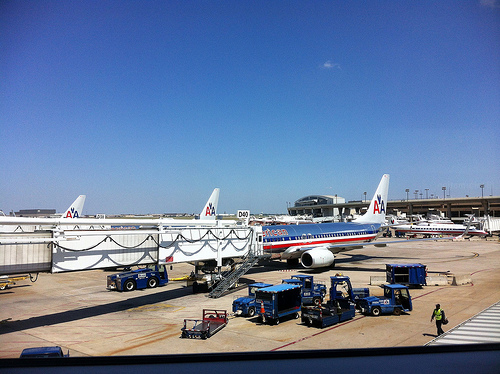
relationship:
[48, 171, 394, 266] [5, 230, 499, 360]
airplanes on runway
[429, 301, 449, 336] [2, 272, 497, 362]
man walking on runway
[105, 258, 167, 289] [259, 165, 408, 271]
machine parked near airplane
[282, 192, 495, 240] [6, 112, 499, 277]
building in background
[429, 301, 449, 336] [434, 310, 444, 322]
man wearing vest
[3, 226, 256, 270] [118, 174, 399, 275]
an extension between planes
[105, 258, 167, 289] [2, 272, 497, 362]
machine on runway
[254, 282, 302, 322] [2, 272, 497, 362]
blue machine on runway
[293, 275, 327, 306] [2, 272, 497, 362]
machine on runway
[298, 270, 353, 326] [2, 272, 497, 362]
blue vehicle on runway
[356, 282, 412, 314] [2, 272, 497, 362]
machine on runway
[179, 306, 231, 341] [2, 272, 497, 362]
machine on runway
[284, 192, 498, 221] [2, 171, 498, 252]
terminal in background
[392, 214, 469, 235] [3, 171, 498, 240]
airplane in background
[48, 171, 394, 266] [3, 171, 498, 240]
airplanes in background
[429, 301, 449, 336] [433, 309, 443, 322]
man wearing a green vest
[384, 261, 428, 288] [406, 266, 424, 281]
luggage cart has a curtain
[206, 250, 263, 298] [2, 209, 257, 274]
ladder leading to gate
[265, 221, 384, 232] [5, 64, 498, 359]
paint sparkles in sunshine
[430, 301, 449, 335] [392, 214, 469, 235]
airport worker working on airplane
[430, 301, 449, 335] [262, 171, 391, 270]
airport worker working on plane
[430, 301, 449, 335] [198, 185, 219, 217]
airport worker working on plane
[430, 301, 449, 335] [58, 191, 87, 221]
airport worker working on plane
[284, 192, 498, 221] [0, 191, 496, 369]
terminal on or side of airport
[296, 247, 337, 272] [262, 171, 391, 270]
engine on plane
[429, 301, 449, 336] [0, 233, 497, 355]
man walking on cement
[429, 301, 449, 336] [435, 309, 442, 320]
man in vest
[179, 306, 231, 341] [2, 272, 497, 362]
machine on a runway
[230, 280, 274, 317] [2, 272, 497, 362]
vehicle on runway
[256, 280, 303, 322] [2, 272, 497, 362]
luggage cart on runway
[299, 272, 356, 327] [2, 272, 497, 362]
vehicle on runway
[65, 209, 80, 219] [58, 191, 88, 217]
aa on a plane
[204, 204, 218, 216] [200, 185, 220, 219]
aa on a plane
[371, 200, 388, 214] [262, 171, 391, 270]
aa on a plane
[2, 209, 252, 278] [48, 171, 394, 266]
ramp to airplanes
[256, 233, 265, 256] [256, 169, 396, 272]
exit door on plane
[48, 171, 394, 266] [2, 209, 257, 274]
airplanes at gate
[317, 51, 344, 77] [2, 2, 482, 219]
cloud in sky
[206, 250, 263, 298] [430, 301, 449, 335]
ladder for airport worker